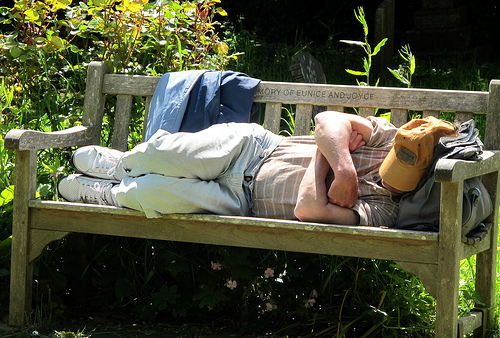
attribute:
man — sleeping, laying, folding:
[53, 104, 473, 232]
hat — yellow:
[378, 115, 456, 196]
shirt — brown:
[248, 117, 404, 228]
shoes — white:
[49, 138, 128, 212]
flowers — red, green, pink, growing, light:
[153, 242, 343, 323]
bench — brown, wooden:
[1, 59, 499, 336]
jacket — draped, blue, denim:
[144, 58, 261, 142]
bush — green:
[1, 2, 247, 221]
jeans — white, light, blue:
[118, 115, 283, 219]